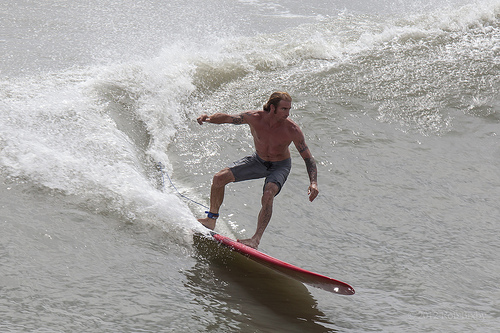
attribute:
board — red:
[210, 230, 355, 295]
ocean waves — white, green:
[59, 182, 168, 257]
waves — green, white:
[241, 30, 484, 67]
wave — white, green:
[298, 2, 498, 76]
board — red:
[172, 194, 374, 331]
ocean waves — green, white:
[141, 182, 193, 240]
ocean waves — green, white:
[25, 95, 98, 157]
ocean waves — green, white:
[96, 62, 166, 112]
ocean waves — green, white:
[183, 35, 239, 80]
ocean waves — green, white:
[298, 31, 345, 59]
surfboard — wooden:
[207, 229, 355, 294]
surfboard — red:
[208, 221, 376, 309]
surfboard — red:
[214, 226, 360, 299]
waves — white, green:
[0, 0, 497, 331]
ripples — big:
[44, 229, 121, 309]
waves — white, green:
[163, 42, 392, 67]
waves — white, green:
[50, 20, 482, 147]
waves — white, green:
[14, 68, 204, 241]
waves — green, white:
[9, 234, 137, 327]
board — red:
[200, 225, 359, 300]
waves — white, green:
[4, 2, 499, 265]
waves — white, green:
[60, 30, 187, 195]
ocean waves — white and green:
[328, 17, 427, 91]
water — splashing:
[22, 17, 389, 70]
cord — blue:
[156, 169, 210, 218]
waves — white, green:
[12, 43, 184, 216]